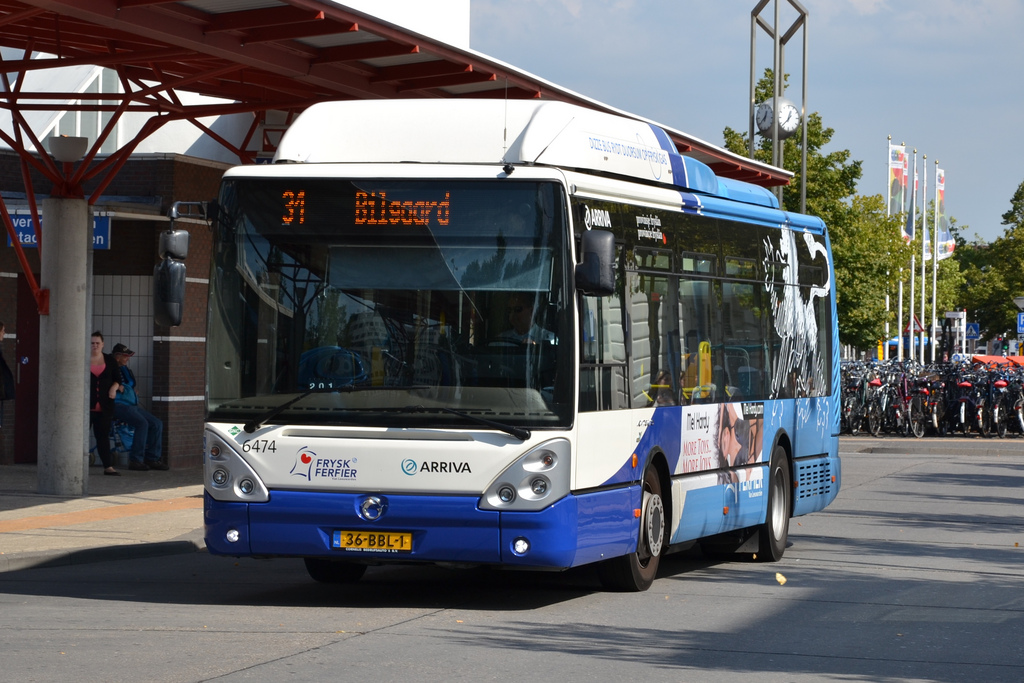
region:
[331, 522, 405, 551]
license plate on the bus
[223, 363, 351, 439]
windshield wiper on the bus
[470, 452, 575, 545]
headlight on the bus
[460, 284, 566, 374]
driver operating the bus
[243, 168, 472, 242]
electric sign on the bus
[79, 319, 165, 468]
people sitting in the bus stop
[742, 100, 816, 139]
clocks on the pole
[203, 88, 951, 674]
bus on a road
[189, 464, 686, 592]
dark blue trim on bus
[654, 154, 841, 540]
light blue trim on bus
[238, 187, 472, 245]
a digital bus sign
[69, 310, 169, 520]
people on the side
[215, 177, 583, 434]
front window on bus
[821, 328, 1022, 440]
bikes in the background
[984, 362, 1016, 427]
motorcycle parked behind the blue bus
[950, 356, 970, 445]
motorcycle parked behind the blue bus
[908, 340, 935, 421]
motorcycle parked behind the blue bus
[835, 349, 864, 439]
motorcycle parked behind the blue bus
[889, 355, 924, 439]
motorcycle parked behind the blue bus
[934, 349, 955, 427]
motorcycle parked behind the blue bus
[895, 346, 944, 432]
motorcycle parked behind the blue bus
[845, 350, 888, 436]
motorcycle parked behind the blue bus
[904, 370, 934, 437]
A two wheeled bicycle.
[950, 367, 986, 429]
A two wheeled bicycle.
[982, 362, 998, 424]
A two wheeled bicycle.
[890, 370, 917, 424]
A two wheeled bicycle.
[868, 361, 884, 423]
A two wheeled bicycle.